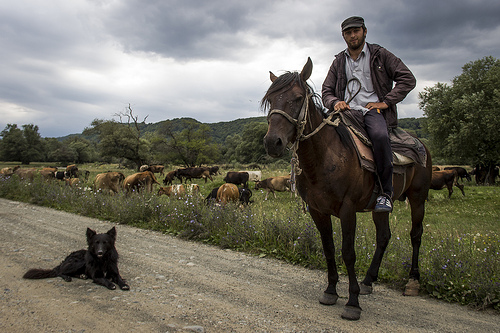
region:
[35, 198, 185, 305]
the dog is black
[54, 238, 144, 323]
the dog is black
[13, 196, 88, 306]
the dog is black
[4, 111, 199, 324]
the dog is black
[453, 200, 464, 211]
Small patch of green grass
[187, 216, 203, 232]
Purple flowers in front of the grass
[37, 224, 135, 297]
Black dog laying on the ground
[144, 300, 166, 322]
Gray and black dirt road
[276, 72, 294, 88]
Black hair of horse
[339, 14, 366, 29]
Gray hat of man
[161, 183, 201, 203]
White and brown cattle in grass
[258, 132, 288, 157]
Black nose of horse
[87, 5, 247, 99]
Mostly cloudy sky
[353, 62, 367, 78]
Gray shirt of the man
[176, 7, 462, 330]
A man on horseback.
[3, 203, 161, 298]
A black dog laying in road.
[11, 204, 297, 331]
An unpaved road.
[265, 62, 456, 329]
A brown horse.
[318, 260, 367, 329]
The horse's front hooves.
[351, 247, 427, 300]
A horse's rear hooves.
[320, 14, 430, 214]
A blue and white tennis shoe.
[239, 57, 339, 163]
Halter on a horse's head.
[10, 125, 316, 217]
A herd of cattle in a field.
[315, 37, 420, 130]
A long sleeve jacket.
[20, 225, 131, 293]
a black dog laying down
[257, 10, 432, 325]
a man sitting on a horse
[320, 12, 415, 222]
a man wearing a brown hat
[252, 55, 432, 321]
a large brown horse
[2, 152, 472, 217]
a group of cows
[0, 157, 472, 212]
a herd of cows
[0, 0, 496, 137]
a dark gloomy sky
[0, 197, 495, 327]
a gravel road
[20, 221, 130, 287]
a black herd dog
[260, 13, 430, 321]
a man riding a horse